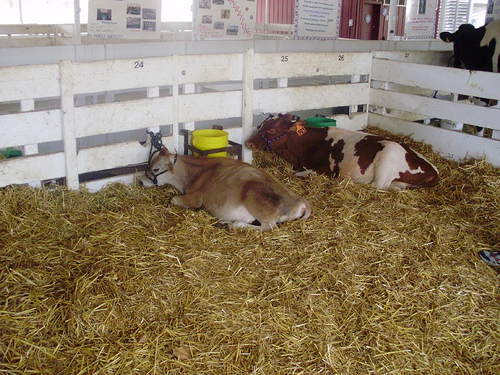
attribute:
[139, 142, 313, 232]
cow — light brown, young, black, white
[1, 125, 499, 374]
hay — light brown, yellow, golden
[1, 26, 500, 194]
fence — wood, white, wooden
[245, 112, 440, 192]
cow — brown, white, lying down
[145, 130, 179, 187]
harness — dark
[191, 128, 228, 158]
bucket — yellow, bright yellow, green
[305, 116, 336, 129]
bucket — green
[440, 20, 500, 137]
cow — black, white, standing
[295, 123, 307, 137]
tag — orange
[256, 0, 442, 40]
wall — maroon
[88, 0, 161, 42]
poster — white